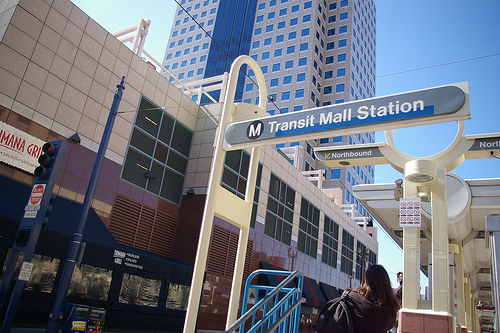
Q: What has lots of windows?
A: The building.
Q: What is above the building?
A: The sky.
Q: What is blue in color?
A: The sky.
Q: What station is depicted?
A: Transit mall station.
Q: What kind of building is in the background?
A: Skyscraper.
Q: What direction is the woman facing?
A: Away from camera.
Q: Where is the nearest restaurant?
A: Grill on the left.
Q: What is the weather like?
A: Sunny.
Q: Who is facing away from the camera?
A: Woman with backpack.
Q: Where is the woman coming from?
A: Staircase.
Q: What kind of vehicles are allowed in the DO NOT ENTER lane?
A: Buses.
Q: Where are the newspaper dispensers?
A: Lower left.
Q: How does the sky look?
A: Blue.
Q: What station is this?
A: Transit mall station.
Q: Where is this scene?
A: At a transit station.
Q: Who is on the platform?
A: A woman with a backpack.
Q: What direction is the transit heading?
A: Northbound.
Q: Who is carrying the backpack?
A: Woman on the platform.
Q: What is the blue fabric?
A: Awning.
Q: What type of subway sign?
A: Directional.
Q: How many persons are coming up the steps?
A: One.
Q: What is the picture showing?
A: A subway entrance.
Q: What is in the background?
A: Skyscrapers.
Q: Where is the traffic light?
A: On the left.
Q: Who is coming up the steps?
A: A woman.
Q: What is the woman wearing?
A: A backpack.